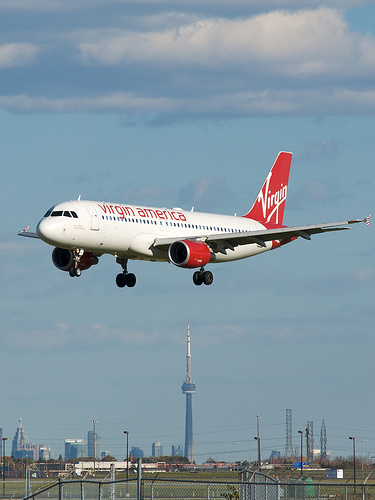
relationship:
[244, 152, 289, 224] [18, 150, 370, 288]
tail of airplane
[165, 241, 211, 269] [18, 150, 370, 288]
engine of airplane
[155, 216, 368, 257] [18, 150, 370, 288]
wing of airplane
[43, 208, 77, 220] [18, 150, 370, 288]
windshield of airplane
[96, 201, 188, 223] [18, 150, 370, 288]
writing on airplane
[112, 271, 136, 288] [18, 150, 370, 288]
wheel of airplane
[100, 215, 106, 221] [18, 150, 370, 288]
window on airplane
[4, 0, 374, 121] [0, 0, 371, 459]
clouds in sky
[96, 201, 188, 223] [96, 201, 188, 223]
writing reads writing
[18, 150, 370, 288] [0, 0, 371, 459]
airplane in sky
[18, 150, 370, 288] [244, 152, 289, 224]
airplane has a tail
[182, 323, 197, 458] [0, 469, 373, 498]
tower near airport